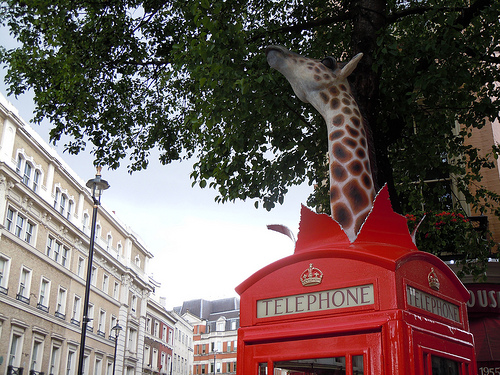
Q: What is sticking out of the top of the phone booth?
A: Giraffe.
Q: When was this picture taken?
A: Daytime.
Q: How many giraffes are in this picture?
A: One.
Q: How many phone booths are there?
A: One.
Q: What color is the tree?
A: Green.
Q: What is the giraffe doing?
A: Eating.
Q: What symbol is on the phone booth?
A: Crown.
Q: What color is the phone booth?
A: Red.